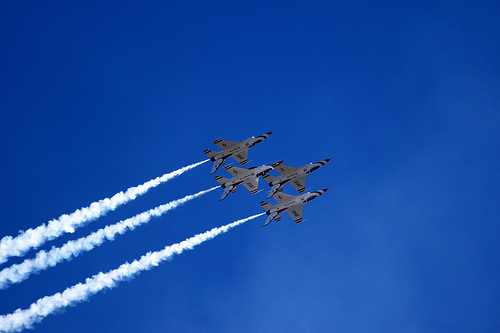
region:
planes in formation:
[198, 115, 332, 229]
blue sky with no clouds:
[102, 66, 154, 108]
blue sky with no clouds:
[368, 199, 415, 247]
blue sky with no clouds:
[245, 256, 306, 330]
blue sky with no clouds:
[341, 55, 416, 110]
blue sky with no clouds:
[381, 65, 452, 115]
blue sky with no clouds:
[97, 51, 169, 112]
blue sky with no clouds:
[230, 55, 322, 119]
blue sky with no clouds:
[58, 28, 120, 90]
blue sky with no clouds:
[42, 111, 104, 175]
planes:
[128, 126, 195, 211]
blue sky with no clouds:
[305, 21, 357, 52]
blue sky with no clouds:
[337, 248, 394, 299]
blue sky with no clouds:
[242, 279, 299, 309]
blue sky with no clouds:
[380, 125, 447, 169]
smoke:
[115, 166, 196, 291]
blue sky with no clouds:
[132, 68, 187, 116]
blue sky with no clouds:
[320, 58, 394, 105]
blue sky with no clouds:
[221, 81, 269, 101]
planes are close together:
[202, 97, 362, 247]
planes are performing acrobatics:
[185, 88, 330, 233]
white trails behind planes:
[5, 103, 227, 330]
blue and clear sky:
[31, 33, 192, 154]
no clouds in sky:
[28, 27, 260, 159]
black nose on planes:
[252, 118, 282, 143]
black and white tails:
[197, 131, 274, 175]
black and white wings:
[191, 105, 301, 212]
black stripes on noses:
[311, 147, 323, 177]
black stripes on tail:
[248, 190, 288, 231]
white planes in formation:
[140, 96, 362, 261]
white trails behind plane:
[32, 138, 252, 318]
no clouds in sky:
[272, 68, 459, 178]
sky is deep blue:
[313, 7, 438, 176]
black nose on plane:
[326, 151, 336, 168]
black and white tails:
[260, 194, 275, 224]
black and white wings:
[271, 138, 306, 200]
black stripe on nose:
[305, 187, 332, 201]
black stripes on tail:
[211, 174, 239, 208]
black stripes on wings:
[263, 187, 302, 224]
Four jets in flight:
[194, 119, 341, 229]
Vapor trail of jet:
[39, 209, 102, 229]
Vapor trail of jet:
[45, 236, 110, 251]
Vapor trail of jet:
[46, 293, 94, 309]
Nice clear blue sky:
[281, 257, 391, 308]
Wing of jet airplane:
[286, 209, 308, 225]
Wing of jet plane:
[211, 136, 226, 146]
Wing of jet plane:
[230, 145, 250, 160]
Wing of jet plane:
[270, 185, 291, 200]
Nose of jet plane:
[311, 184, 333, 204]